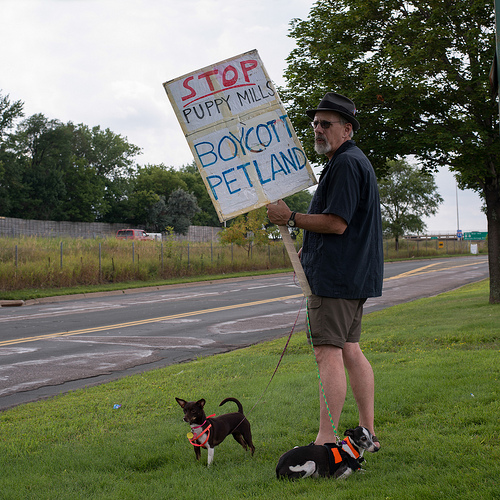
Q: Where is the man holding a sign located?
A: On the side of the road.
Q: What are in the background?
A: Trees.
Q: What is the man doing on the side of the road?
A: Holding a sign protesting.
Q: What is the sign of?
A: Protesting puppy mills.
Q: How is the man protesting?
A: In bare legs.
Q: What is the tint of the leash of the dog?
A: Orange.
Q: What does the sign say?
A: Stop puppy mills.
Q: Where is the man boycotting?
A: Standing on grass.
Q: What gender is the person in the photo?
A: Male.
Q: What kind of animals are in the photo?
A: Dogs.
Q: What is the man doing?
A: Protesting.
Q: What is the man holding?
A: A sign.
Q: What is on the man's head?
A: A hat.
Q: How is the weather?
A: Cloudy.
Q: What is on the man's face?
A: Glasses.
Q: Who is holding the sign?
A: An old man.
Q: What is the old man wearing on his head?
A: A fedora.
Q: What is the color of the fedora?
A: Black.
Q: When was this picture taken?
A: During the day.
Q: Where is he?
A: By a road on grassy field.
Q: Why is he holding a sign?
A: Because he wants to boycott petland.